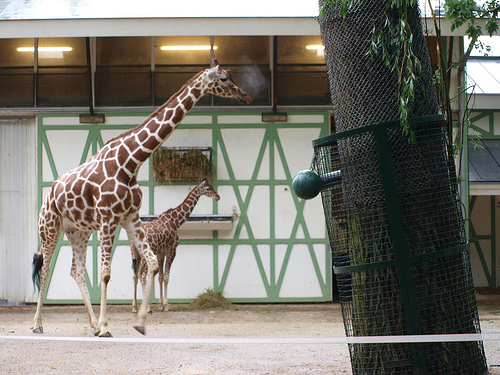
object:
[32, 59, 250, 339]
giraffe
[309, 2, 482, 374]
tree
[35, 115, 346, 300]
wall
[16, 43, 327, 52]
lights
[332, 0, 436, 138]
moss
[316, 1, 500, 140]
leaves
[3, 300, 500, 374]
ground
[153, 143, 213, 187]
basket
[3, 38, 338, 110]
windows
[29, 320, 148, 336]
hooves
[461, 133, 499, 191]
roofing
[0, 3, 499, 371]
photo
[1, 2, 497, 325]
building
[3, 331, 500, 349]
string